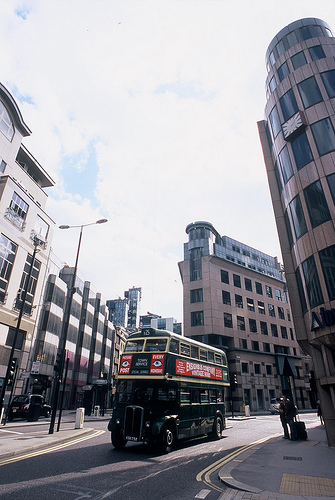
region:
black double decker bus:
[108, 319, 245, 460]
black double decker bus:
[101, 308, 237, 463]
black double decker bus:
[108, 314, 235, 457]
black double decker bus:
[102, 322, 233, 449]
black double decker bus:
[94, 320, 233, 450]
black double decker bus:
[88, 314, 230, 454]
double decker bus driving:
[107, 328, 226, 451]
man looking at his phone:
[270, 398, 289, 439]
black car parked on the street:
[6, 394, 50, 420]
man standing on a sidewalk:
[271, 396, 290, 438]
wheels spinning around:
[154, 427, 176, 453]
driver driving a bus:
[122, 386, 150, 400]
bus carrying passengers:
[106, 326, 228, 450]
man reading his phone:
[271, 397, 290, 439]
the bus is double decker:
[118, 337, 229, 452]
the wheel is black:
[159, 433, 185, 458]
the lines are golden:
[206, 435, 264, 483]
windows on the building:
[216, 270, 297, 358]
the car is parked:
[12, 390, 51, 417]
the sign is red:
[172, 358, 229, 382]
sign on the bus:
[173, 357, 223, 384]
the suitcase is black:
[290, 421, 306, 441]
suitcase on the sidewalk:
[289, 420, 311, 442]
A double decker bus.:
[102, 322, 235, 450]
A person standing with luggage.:
[270, 389, 307, 436]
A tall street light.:
[46, 216, 110, 438]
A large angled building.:
[174, 218, 319, 409]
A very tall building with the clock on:
[271, 17, 320, 290]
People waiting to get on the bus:
[259, 383, 303, 454]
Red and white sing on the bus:
[170, 359, 225, 379]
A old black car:
[5, 373, 59, 424]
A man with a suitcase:
[283, 394, 305, 441]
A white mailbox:
[65, 395, 96, 452]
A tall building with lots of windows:
[198, 284, 278, 406]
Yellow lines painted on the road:
[205, 435, 259, 489]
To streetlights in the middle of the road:
[35, 209, 114, 297]